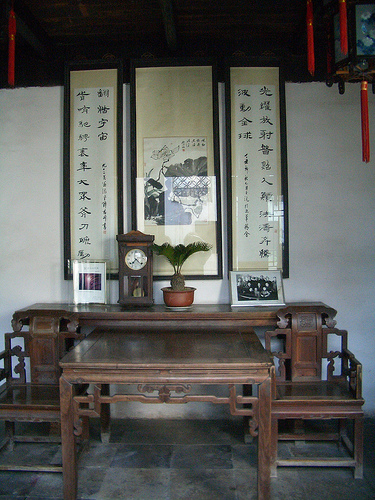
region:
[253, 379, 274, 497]
a brown table leg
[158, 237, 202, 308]
a plant on a table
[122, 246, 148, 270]
a face of a clock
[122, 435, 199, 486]
tile on the floor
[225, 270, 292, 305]
a photo in a frame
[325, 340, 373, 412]
an arm of a chair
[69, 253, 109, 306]
a picture in a frame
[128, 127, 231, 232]
a picture in a frame on a wall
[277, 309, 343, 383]
the back of a chair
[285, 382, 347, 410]
the seat of a chair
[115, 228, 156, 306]
small wooden clock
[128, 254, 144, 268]
two black clock hands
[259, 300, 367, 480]
wooden chair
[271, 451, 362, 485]
color of wood is fading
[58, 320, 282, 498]
tall brown wooden table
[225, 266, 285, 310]
rectangular picture frame with a black and white photo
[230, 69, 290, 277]
tall, rectangular frame with Chinese writing in it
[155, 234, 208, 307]
small green plant in a brownish pot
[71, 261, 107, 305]
light reflecting off of picture frame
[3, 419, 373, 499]
stone tiles on the floor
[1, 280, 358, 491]
ANTIQUE DESK AND CHAIRS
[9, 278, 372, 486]
ANTIQUE FURNITURE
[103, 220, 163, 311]
ANTIQUE TABLE CLOCK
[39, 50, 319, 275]
JAPANESE PICTURE FRAME ON THE WALL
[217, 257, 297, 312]
Old black and white photo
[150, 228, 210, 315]
Bonsai plant on the table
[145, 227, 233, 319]
Small palm tree on the desk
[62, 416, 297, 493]
Tiled floor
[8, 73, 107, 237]
White wall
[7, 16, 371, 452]
Japanese furniture and decor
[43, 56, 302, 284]
three long black picture frames hanging on wall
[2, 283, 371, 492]
a vintage wood desk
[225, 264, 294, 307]
a framed black and white picture on the desk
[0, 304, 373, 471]
two wood chairs attached at each end of table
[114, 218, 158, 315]
a wood clock on table leaning against wall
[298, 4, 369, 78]
red tassels hanging from ceiling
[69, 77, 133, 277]
chinese markings on white paper in picture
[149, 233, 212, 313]
a plant in a brown bowl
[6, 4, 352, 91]
a ceiling make of wood boards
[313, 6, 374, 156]
a light on the ceiling with red tassel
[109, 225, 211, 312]
wooden clock next to the plant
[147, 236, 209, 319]
green plant in round orange pot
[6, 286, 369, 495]
two wooden chairs on each side of the table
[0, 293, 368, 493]
two chairs face towards the camera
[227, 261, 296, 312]
people in a black and white photo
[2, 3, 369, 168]
red tassels hang from the ceiling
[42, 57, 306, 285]
3 framed banners hang on the white wall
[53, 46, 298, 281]
the middle banner is the largest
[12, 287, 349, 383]
wooden display shelf against the wall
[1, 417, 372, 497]
floor has square stone pattern